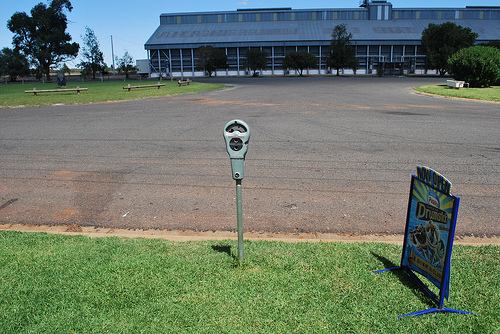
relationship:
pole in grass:
[233, 179, 246, 259] [2, 229, 484, 331]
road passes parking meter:
[0, 77, 499, 238] [224, 117, 256, 262]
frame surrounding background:
[391, 162, 462, 303] [403, 178, 453, 287]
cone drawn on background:
[404, 221, 445, 266] [403, 200, 453, 287]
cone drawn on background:
[428, 237, 446, 267] [403, 200, 453, 287]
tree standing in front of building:
[325, 22, 356, 76] [142, 1, 484, 78]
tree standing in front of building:
[277, 48, 318, 77] [142, 1, 484, 78]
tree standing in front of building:
[192, 42, 232, 76] [142, 1, 484, 78]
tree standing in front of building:
[417, 20, 478, 76] [142, 1, 484, 78]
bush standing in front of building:
[442, 42, 483, 87] [142, 1, 484, 78]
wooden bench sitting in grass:
[120, 81, 170, 91] [1, 78, 234, 110]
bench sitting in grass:
[172, 68, 196, 95] [2, 80, 234, 105]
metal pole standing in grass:
[220, 118, 250, 277] [2, 229, 484, 331]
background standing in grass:
[403, 178, 453, 287] [4, 215, 496, 331]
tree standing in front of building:
[242, 46, 270, 80] [142, 1, 484, 78]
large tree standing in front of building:
[418, 19, 471, 61] [142, 1, 484, 78]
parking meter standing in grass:
[218, 119, 252, 176] [2, 229, 484, 331]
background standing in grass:
[403, 178, 453, 287] [2, 229, 484, 331]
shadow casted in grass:
[209, 233, 244, 264] [2, 229, 484, 331]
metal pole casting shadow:
[220, 118, 250, 277] [209, 233, 244, 264]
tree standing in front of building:
[281, 50, 317, 77] [142, 1, 484, 78]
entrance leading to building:
[377, 59, 404, 78] [131, 5, 498, 82]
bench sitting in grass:
[443, 77, 465, 89] [413, 82, 499, 100]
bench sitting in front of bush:
[443, 77, 465, 89] [444, 44, 497, 86]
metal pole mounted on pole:
[220, 118, 250, 277] [234, 180, 245, 270]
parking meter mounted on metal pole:
[204, 112, 271, 177] [212, 145, 266, 277]